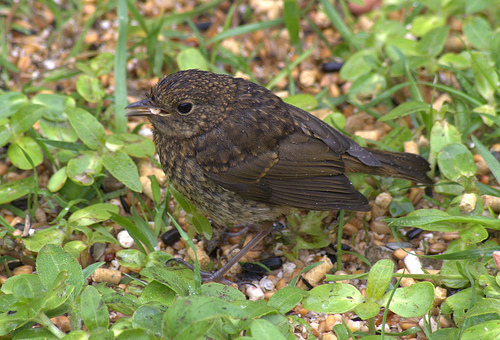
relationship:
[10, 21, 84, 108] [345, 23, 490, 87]
rocks in grass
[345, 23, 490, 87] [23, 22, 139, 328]
grass on ground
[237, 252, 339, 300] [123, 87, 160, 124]
seed in beak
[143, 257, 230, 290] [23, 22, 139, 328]
feet on ground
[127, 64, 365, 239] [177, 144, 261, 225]
bird has feathers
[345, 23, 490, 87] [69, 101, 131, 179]
grass has leaves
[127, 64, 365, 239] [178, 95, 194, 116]
bird has eye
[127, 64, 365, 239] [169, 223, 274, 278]
bird has legs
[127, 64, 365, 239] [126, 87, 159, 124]
bird has beak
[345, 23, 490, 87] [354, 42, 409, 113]
grass has tip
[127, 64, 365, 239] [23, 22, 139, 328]
bird on ground